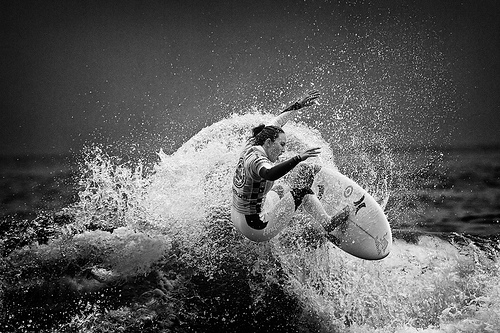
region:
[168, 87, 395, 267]
a woman surfing a wave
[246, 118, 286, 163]
the head of a woman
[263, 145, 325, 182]
the arm of a woman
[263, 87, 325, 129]
the arm of a woman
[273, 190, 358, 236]
the leg of a woman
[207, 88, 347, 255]
a woman wearing a wet suit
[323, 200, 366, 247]
the foot of the surfer on the surfboard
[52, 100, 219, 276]
the splash from a surfboard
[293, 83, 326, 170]
the hands of a woman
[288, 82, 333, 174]
the hands of a surfer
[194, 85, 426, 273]
surfer splashing in the water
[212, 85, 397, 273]
surfer splashing in the water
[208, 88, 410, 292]
surfer splashing in the water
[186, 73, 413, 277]
surfer splashing in the water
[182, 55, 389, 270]
surfer splashing in the water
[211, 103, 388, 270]
surfer splashing in the water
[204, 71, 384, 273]
surfer splashing in the water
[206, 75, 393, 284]
surfer splashing in the water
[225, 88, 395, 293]
surfer splashing in the water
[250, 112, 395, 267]
surfer splashing in the water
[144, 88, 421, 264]
a female surfer jumping a wave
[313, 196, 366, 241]
the surfer's foot on the board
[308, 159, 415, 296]
the surfboard jumping out of the water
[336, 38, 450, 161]
water droplets of seawater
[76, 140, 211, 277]
the splash of the surfboard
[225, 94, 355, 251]
the surfer in a white and black wetsuit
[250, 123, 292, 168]
the head of the surfer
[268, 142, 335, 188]
the arm of the surfer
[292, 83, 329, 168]
the hands of the surfer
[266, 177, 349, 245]
the legs of a surfer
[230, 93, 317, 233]
Athletic person on board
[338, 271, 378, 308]
Churning white ocean water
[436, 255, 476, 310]
Churning white ocean water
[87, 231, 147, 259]
Churning white ocean water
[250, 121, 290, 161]
Head of athletic surfer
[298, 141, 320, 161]
Hand of athletic surfer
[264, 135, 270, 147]
Ear of athletic surfer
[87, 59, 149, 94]
Hazy ocean sky overhead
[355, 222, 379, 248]
Part of athlete's surfboard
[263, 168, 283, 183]
Elbow of athletic surfer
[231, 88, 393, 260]
woman is on a surfboard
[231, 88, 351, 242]
surfer has her arms in the air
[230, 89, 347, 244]
surfer's arms are up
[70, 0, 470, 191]
drops of water in the air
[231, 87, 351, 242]
surfer is wearing a wetsuit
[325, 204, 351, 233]
bare feet on a surfboard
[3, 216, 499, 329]
crest of a wave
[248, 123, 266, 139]
ponytail in woman's hair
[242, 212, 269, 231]
black design on hip of wet suit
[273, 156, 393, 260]
surf board the man is riding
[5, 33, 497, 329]
splash caused by mans surf board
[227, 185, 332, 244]
mans white wet pants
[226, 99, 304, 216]
mans multi colored wet suit top